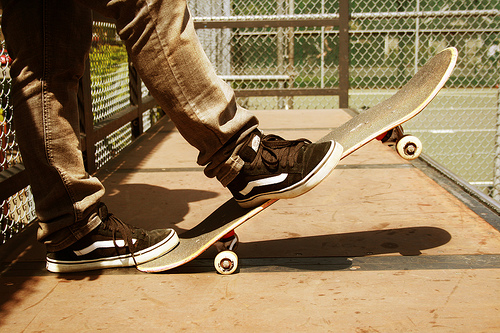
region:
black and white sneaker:
[226, 131, 343, 203]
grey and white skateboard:
[143, 46, 468, 275]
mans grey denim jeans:
[2, 1, 252, 247]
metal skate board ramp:
[366, 116, 499, 211]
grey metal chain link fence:
[198, 5, 496, 85]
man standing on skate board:
[3, 2, 450, 269]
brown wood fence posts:
[192, 2, 352, 116]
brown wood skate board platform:
[6, 108, 493, 332]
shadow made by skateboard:
[233, 223, 455, 270]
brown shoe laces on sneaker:
[101, 202, 141, 277]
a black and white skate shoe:
[220, 133, 342, 212]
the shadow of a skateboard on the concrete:
[218, 219, 453, 288]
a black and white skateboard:
[144, 41, 464, 285]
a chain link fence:
[193, 2, 499, 197]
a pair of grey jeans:
[11, 0, 265, 243]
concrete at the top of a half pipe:
[0, 110, 495, 327]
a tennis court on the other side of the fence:
[237, 82, 498, 182]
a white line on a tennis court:
[417, 120, 498, 134]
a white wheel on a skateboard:
[396, 133, 426, 162]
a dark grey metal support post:
[332, 3, 362, 110]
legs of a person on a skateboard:
[7, 1, 345, 286]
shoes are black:
[31, 114, 363, 306]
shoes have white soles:
[16, 130, 349, 280]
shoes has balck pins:
[41, 116, 357, 287]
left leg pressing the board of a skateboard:
[28, 198, 208, 291]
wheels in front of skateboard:
[369, 123, 432, 173]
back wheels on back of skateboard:
[205, 233, 245, 280]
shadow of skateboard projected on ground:
[250, 210, 486, 289]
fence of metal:
[202, 0, 495, 98]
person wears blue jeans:
[6, 8, 358, 285]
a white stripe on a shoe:
[239, 175, 289, 189]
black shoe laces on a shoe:
[110, 217, 137, 242]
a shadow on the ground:
[268, 214, 450, 269]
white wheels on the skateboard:
[207, 250, 257, 276]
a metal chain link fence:
[287, 9, 454, 46]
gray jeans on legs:
[11, 18, 242, 228]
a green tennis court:
[441, 109, 488, 176]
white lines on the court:
[428, 123, 495, 135]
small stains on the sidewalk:
[310, 251, 457, 323]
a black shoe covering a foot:
[235, 135, 328, 199]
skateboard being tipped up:
[118, 48, 465, 285]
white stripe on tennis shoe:
[236, 171, 294, 201]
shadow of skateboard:
[216, 219, 463, 277]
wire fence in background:
[450, 122, 494, 175]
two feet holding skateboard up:
[36, 124, 364, 274]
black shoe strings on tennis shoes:
[256, 132, 314, 167]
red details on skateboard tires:
[209, 227, 245, 279]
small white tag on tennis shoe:
[249, 131, 261, 151]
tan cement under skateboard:
[296, 259, 486, 331]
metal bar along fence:
[195, 18, 355, 30]